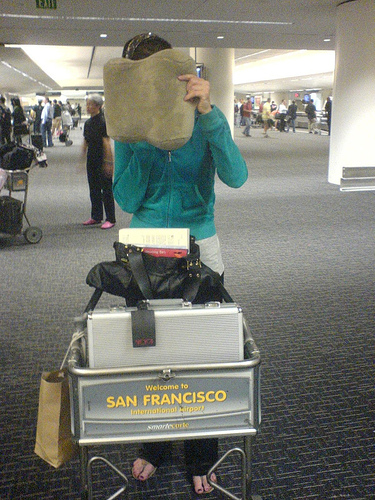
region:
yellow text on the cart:
[106, 382, 225, 430]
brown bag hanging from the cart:
[33, 328, 85, 468]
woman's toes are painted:
[131, 462, 145, 478]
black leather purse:
[86, 242, 216, 301]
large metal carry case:
[90, 300, 244, 358]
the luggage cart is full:
[2, 140, 40, 244]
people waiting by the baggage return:
[232, 95, 331, 131]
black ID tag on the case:
[131, 307, 155, 347]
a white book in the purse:
[118, 226, 189, 260]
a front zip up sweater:
[113, 106, 248, 236]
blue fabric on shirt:
[201, 224, 216, 229]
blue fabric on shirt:
[150, 218, 166, 219]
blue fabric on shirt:
[192, 202, 210, 203]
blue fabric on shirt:
[169, 191, 181, 195]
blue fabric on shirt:
[153, 180, 161, 186]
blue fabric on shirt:
[217, 164, 228, 168]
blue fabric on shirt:
[122, 189, 134, 200]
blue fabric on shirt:
[142, 169, 162, 172]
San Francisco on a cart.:
[102, 387, 226, 409]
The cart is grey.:
[60, 339, 264, 492]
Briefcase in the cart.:
[65, 298, 241, 363]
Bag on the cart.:
[25, 358, 72, 471]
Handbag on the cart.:
[92, 245, 219, 305]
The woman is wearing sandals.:
[128, 449, 223, 498]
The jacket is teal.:
[118, 137, 219, 235]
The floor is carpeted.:
[240, 255, 373, 462]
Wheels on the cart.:
[21, 222, 49, 249]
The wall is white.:
[334, 12, 374, 177]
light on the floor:
[263, 220, 347, 278]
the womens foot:
[133, 459, 155, 477]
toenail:
[196, 486, 204, 492]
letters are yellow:
[104, 390, 224, 407]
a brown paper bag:
[36, 371, 64, 464]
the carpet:
[266, 348, 358, 432]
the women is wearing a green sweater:
[148, 166, 208, 220]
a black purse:
[106, 262, 183, 292]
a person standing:
[77, 91, 108, 228]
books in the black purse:
[127, 227, 189, 255]